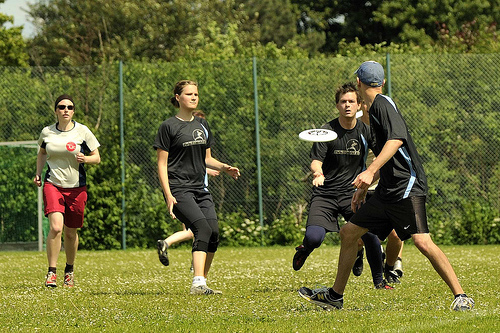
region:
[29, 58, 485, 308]
group of men and women playing frisbee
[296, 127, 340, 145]
white frisbee thrown mid air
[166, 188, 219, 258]
girl wearing black running pants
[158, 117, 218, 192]
girl wearing black te shirt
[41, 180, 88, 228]
woman wearing red shorts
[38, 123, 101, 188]
woman wearing white shirt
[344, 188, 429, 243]
man wearing black Nike shorts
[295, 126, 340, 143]
frisbee is white and it is in the air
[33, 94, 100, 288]
the person is running with red shorts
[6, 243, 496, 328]
grasses in the ground are green in color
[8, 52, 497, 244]
blue color poles are fixed on the ground for supporting the fence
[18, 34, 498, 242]
trees and bushes are grown behind the fence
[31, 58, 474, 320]
people are playing frisbee in the grass field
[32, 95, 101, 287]
the woman is wearing sun glasses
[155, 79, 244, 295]
the person is wearing knee bands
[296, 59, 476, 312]
the guy is wearing a blue color cap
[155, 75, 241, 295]
Woman in black shirt and black shorts.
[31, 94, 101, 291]
Woman wearing red shorts and sunglasses.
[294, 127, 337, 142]
White plastic frisbee in the air.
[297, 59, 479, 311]
Man wearing blue baseball cap and sneakers.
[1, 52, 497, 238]
A green chain-link fence separated by green poles.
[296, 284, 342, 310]
Dark blue New Balance sneaker with light blue laces.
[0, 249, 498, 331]
Field of grass with white clover flowers.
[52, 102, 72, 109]
A pair of rectangular black sunglasses.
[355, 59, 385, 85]
Top of a blue baseball cap.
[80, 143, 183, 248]
Leafy shrub growing behind fence.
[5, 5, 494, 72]
bits of sky and trees behind tops of bushes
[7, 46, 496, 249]
chain-link fence in front of tall green bushes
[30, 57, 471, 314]
males and females playing frisbee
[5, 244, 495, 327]
yellowish-green grass covering ground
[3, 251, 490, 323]
small white flowers growing on top of grass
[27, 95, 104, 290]
young woman in sunglasses running straight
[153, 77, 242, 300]
young woman in black angling toward side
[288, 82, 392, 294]
white frisbee heading toward man in black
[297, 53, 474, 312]
man with wide stride turning head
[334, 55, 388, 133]
head of person mostly hidden behind two others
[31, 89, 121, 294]
Woman in white top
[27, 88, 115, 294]
Woman in red shorts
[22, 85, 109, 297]
Woman wearing sunglasses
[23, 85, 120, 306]
Woman wearing red shoes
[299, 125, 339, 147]
frisbee in mid air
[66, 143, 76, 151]
red emblem on the girl's shirt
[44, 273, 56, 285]
red shoe the girl is wearing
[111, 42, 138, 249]
green pole supporting the fence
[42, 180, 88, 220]
red shorts the woman is wearing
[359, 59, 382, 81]
blue cap the man is wearing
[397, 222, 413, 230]
nike emblem on the black shorts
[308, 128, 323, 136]
black design on the frisbee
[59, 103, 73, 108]
woman's sunglasses on her face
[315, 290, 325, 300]
yellow emblem on the black shoes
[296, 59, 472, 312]
man wearing blue cap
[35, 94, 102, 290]
woman wearing red shorts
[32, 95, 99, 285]
woman wearing black sunglasses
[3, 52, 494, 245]
fence with green poles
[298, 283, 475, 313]
laces on the shoes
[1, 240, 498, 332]
ground is grass covered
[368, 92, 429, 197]
black shirt with blue stripe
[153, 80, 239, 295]
woman wearing black shirt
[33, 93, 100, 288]
woman wearing red sneakers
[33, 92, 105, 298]
woman in red shorts